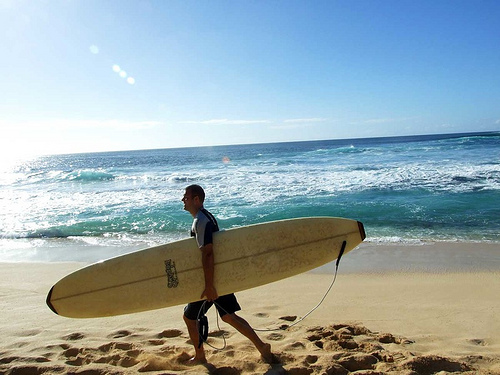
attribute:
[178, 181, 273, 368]
man — facing, walking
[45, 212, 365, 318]
surfboard — white, ended, pointing, black tipped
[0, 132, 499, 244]
ocean — blue, sunny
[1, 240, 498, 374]
beach — wet, beautiful, sandy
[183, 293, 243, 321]
shorts — black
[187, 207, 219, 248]
shirt — short, gray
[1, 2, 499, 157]
sky — cloudless, cloudy, blue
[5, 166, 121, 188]
wave — white, small, crashing